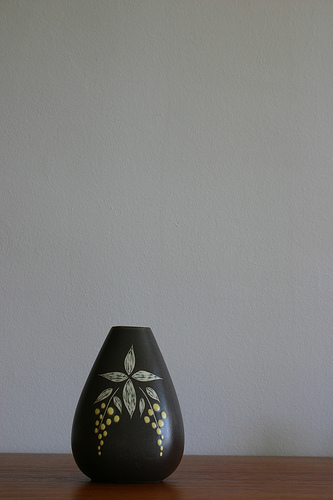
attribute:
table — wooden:
[226, 455, 294, 487]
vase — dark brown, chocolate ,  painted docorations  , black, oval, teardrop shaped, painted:
[69, 325, 186, 484]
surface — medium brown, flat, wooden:
[3, 450, 331, 498]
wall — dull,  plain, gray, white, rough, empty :
[0, 0, 331, 455]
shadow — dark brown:
[68, 483, 181, 498]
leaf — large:
[120, 375, 136, 416]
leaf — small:
[137, 395, 144, 414]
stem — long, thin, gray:
[136, 384, 158, 422]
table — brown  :
[6, 446, 315, 493]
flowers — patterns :
[111, 352, 157, 413]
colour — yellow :
[146, 397, 168, 450]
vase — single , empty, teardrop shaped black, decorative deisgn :
[70, 315, 187, 490]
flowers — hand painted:
[102, 342, 163, 423]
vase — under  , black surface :
[60, 311, 188, 495]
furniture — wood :
[5, 451, 322, 493]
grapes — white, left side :
[87, 390, 123, 458]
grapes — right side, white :
[138, 399, 177, 455]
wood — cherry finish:
[189, 457, 289, 498]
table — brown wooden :
[213, 460, 313, 498]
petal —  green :
[139, 386, 158, 401]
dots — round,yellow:
[142, 406, 162, 433]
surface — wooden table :
[190, 459, 321, 495]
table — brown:
[0, 448, 333, 498]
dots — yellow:
[91, 395, 120, 456]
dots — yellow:
[143, 399, 169, 456]